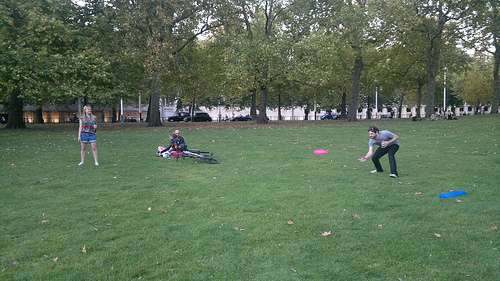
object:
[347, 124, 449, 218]
man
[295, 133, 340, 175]
frisbee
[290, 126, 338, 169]
frisbee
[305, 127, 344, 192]
air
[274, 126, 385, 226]
air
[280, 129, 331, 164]
frisbee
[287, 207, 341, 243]
leaves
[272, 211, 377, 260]
ground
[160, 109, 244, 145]
vehicles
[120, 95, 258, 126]
street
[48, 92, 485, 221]
people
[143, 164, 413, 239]
lawn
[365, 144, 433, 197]
pants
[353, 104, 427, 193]
man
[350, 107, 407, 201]
man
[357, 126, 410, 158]
shirt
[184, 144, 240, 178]
bike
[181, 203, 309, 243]
ground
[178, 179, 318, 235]
park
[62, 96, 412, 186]
people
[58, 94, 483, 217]
game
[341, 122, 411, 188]
person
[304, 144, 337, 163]
frisbee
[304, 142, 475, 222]
frisbees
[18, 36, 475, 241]
air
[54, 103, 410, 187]
people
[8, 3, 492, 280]
day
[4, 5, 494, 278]
daytime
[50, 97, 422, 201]
people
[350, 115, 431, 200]
he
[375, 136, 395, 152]
drink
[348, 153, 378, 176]
hand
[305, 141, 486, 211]
discs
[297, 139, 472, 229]
frisbees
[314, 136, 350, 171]
frisbee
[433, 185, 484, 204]
disc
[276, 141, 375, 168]
frisbee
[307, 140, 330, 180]
frisbee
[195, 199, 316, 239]
patch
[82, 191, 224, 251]
patch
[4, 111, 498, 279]
field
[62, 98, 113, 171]
girl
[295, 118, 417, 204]
person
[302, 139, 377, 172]
frisbee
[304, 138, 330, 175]
frisbee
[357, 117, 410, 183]
person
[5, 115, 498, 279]
grass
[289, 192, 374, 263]
leaves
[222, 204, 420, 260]
leaves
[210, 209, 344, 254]
patch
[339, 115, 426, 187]
guy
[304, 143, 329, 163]
frisbee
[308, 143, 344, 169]
frisbee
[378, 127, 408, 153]
arm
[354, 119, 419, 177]
man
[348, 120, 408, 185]
man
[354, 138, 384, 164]
arm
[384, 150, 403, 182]
legs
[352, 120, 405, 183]
man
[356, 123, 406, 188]
man